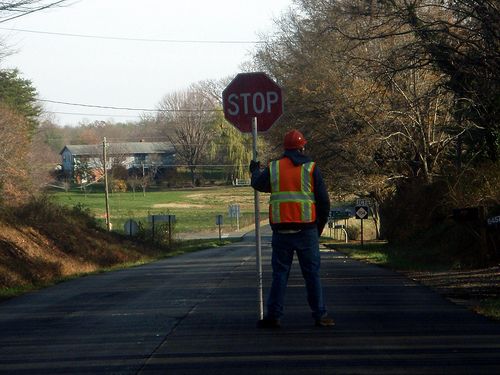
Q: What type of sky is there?
A: A daytime sky.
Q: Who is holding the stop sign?
A: A man.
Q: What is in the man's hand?
A: A stop sign.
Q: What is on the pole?
A: A stop sign.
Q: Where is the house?
A: In the distance.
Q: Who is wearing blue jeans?
A: The man.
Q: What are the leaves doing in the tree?
A: Turning orange.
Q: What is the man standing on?
A: The road.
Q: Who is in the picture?
A: A man.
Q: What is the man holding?
A: Stop sign.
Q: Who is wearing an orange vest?
A: The man.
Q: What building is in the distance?
A: A house.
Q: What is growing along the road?
A: Trees.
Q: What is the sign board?
A: Stop.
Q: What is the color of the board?
A: Red and white.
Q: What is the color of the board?
A: Grey.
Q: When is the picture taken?
A: Daytime.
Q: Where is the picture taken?
A: On a road in a residential area.